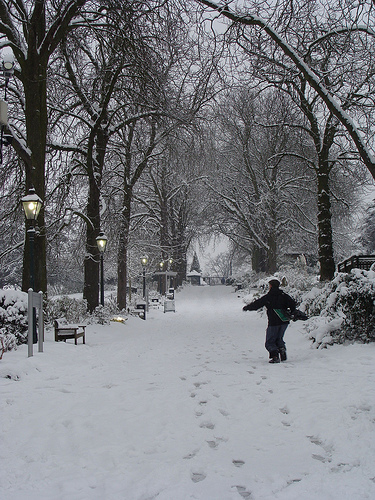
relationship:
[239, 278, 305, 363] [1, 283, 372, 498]
guy walking in snow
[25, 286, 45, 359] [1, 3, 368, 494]
banner in park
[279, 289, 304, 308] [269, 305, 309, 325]
arm holding snowboard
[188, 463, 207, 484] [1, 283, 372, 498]
footstep are in snow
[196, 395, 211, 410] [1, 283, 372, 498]
footstep are in snow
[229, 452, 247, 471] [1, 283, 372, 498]
footstep are in snow